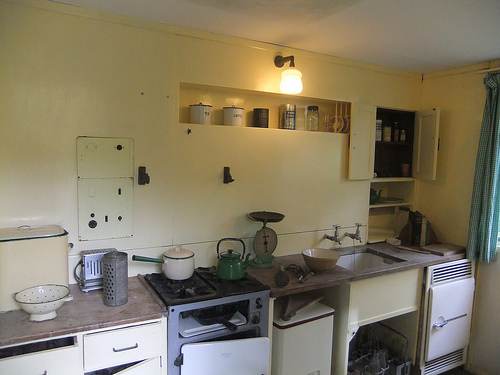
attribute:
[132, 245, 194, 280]
pot — white and green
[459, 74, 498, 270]
curtain — blue and white, checkered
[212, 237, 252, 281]
tea kettle — green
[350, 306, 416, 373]
dishwasher — small, open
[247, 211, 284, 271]
scale — metal, green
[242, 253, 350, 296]
counter — gray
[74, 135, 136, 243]
sockets — left behind, from missing appliance